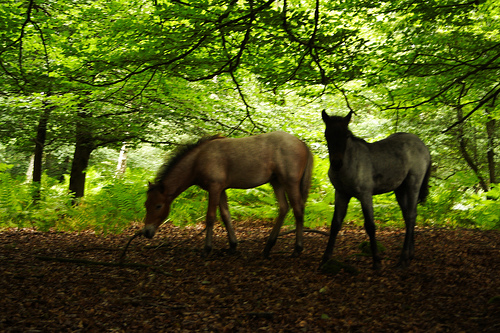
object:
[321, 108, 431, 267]
horse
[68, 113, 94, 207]
trunk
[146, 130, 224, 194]
mane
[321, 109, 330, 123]
ears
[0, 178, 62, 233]
vegetation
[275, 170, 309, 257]
leg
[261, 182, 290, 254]
leg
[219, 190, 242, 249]
leg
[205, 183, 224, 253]
leg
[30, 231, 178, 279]
sticks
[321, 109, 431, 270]
animal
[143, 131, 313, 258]
animal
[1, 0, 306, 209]
tree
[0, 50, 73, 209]
tree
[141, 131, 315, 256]
horse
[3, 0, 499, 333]
woods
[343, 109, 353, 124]
ears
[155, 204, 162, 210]
eye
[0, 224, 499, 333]
leaves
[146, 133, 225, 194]
fur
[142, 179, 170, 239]
head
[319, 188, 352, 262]
front leg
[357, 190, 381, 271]
front leg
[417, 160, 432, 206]
tail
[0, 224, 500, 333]
ground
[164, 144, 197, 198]
neck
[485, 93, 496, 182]
trunk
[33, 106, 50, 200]
trunk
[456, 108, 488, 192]
trunk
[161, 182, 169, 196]
ears